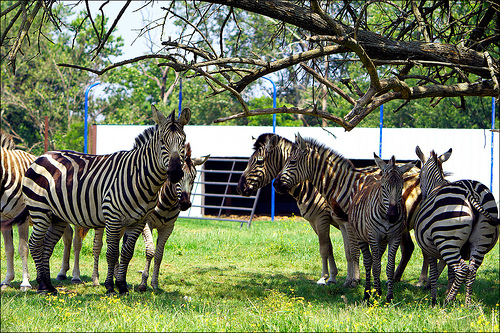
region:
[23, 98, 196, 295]
black and white striped zebra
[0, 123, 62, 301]
black and white striped zebra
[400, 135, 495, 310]
black and white striped zebra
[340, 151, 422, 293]
black and white striped zebra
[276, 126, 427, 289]
black and white striped zebra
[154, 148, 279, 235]
metal tube gate falling into the grass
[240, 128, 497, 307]
group of zebras in the grass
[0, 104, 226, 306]
group of zebras in the grass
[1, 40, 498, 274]
The animals are zebras.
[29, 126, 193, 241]
The zebras are black and white.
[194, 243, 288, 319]
The grass is green.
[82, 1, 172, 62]
The sky is blue.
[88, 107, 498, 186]
The building is white.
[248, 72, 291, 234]
The posts are blue.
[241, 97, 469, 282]
The zebras are striped.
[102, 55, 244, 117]
The leaves are green.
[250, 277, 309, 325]
Yellow flowers growing in the grass.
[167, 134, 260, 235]
The gate is silver.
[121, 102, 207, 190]
Zebra looking directly at camera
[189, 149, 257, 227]
Metal gate leaning against a building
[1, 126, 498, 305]
Eight zebras standing in a field of grass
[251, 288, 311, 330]
Yellow wildflowers growing in the field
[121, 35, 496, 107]
Dead tree limb above zebras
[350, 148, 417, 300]
Baby zebra standing in the grass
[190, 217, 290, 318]
Nice green meadow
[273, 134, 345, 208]
This zebra has a very short mane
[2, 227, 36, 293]
This zebra's legs don't have any stripes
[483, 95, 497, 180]
Blue metal pole standing upright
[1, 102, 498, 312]
Zebras in a zoo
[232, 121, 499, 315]
Zebras are in the shade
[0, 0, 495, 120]
Branches of tree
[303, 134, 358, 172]
Mane of zebra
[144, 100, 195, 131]
Ears os zebra are round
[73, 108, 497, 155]
Building behind zebra pen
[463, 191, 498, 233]
Tail of zebra swing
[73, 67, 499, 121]
Blue poles on zebra pen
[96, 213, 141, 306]
Front legs of zebra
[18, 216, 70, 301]
Back legs of zebra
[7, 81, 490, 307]
7 zebras standing together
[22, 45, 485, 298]
zebras standing on grass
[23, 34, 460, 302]
zebras standing in shade on sunny day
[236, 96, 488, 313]
four zebras standing in shade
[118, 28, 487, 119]
tree with no leaves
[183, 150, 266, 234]
metal fence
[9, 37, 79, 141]
trees with green leaves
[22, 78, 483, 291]
black and white animals standing together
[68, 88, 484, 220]
zebra near white building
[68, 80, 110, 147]
metal blue pole